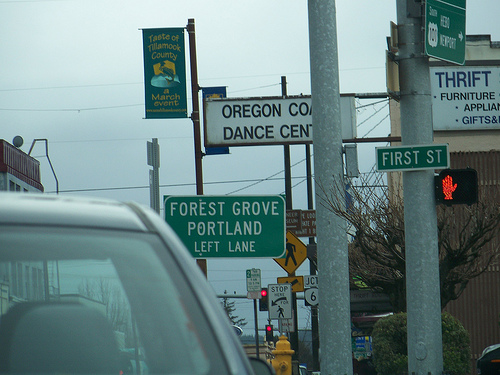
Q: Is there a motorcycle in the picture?
A: No, there are no motorcycles.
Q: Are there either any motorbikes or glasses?
A: No, there are no motorbikes or glasses.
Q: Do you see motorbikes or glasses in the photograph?
A: No, there are no motorbikes or glasses.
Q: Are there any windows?
A: Yes, there is a window.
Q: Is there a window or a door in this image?
A: Yes, there is a window.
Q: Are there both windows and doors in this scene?
A: No, there is a window but no doors.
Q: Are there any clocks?
A: No, there are no clocks.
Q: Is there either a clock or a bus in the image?
A: No, there are no clocks or buses.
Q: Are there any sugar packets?
A: No, there are no sugar packets.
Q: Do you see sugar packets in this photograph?
A: No, there are no sugar packets.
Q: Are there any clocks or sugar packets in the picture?
A: No, there are no sugar packets or clocks.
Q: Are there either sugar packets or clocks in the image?
A: No, there are no sugar packets or clocks.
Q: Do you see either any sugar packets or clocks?
A: No, there are no sugar packets or clocks.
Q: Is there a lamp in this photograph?
A: No, there are no lamps.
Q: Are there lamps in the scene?
A: No, there are no lamps.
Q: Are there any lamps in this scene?
A: No, there are no lamps.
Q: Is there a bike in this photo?
A: No, there are no bikes.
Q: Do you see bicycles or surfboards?
A: No, there are no bicycles or surfboards.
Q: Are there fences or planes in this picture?
A: No, there are no fences or planes.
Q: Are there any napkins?
A: No, there are no napkins.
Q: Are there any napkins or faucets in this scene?
A: No, there are no napkins or faucets.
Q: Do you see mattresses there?
A: No, there are no mattresses.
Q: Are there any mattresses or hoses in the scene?
A: No, there are no mattresses or hoses.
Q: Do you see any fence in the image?
A: No, there are no fences.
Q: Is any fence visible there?
A: No, there are no fences.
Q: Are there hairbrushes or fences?
A: No, there are no fences or hairbrushes.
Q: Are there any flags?
A: Yes, there is a flag.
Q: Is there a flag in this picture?
A: Yes, there is a flag.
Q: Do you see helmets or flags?
A: Yes, there is a flag.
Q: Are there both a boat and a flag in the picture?
A: No, there is a flag but no boats.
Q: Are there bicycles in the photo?
A: No, there are no bicycles.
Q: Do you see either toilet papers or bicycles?
A: No, there are no bicycles or toilet papers.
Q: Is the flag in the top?
A: Yes, the flag is in the top of the image.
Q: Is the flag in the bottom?
A: No, the flag is in the top of the image.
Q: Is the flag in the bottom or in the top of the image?
A: The flag is in the top of the image.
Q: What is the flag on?
A: The flag is on the pole.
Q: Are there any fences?
A: No, there are no fences.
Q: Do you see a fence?
A: No, there are no fences.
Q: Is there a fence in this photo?
A: No, there are no fences.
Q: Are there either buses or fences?
A: No, there are no fences or buses.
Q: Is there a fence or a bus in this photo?
A: No, there are no fences or buses.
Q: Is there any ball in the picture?
A: No, there are no balls.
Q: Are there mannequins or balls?
A: No, there are no balls or mannequins.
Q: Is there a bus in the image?
A: No, there are no buses.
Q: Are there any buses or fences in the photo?
A: No, there are no buses or fences.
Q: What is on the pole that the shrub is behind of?
A: The sign is on the pole.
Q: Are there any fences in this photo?
A: No, there are no fences.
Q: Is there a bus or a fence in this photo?
A: No, there are no fences or buses.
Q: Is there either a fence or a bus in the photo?
A: No, there are no fences or buses.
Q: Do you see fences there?
A: No, there are no fences.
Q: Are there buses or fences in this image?
A: No, there are no fences or buses.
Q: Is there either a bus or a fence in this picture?
A: No, there are no fences or buses.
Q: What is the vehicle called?
A: The vehicle is a car.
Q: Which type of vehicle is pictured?
A: The vehicle is a car.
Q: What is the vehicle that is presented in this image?
A: The vehicle is a car.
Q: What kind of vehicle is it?
A: The vehicle is a car.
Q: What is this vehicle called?
A: That is a car.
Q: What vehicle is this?
A: That is a car.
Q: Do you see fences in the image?
A: No, there are no fences.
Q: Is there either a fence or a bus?
A: No, there are no fences or buses.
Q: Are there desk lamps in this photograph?
A: No, there are no desk lamps.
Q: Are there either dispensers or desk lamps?
A: No, there are no desk lamps or dispensers.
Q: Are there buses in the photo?
A: No, there are no buses.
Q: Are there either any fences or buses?
A: No, there are no buses or fences.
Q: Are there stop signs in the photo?
A: Yes, there is a stop sign.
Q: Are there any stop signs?
A: Yes, there is a stop sign.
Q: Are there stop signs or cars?
A: Yes, there is a stop sign.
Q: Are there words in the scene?
A: Yes, there are words.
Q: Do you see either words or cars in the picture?
A: Yes, there are words.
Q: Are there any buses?
A: No, there are no buses.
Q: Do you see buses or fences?
A: No, there are no buses or fences.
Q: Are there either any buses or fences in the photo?
A: No, there are no buses or fences.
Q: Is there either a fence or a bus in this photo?
A: No, there are no buses or fences.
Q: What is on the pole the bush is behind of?
A: The sign is on the pole.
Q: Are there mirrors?
A: No, there are no mirrors.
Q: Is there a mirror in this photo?
A: No, there are no mirrors.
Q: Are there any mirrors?
A: No, there are no mirrors.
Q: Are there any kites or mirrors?
A: No, there are no mirrors or kites.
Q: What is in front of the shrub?
A: The pole is in front of the shrub.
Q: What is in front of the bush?
A: The pole is in front of the shrub.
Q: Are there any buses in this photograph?
A: No, there are no buses.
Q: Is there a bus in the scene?
A: No, there are no buses.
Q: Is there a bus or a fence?
A: No, there are no buses or fences.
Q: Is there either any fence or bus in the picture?
A: No, there are no buses or fences.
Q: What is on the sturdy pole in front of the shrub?
A: The sign is on the pole.